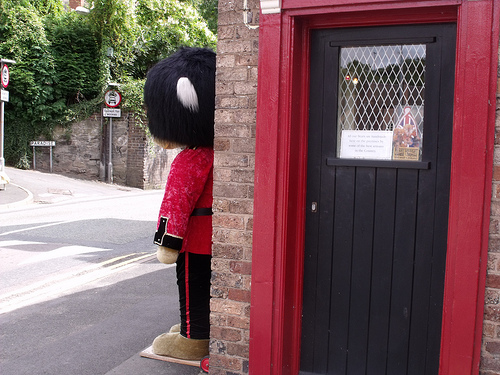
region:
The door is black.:
[307, 179, 387, 343]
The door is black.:
[336, 227, 399, 362]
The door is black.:
[322, 58, 437, 370]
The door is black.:
[303, 48, 398, 320]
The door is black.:
[360, 130, 400, 330]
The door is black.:
[365, 80, 432, 341]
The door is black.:
[365, 171, 413, 369]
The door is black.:
[357, 214, 394, 342]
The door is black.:
[330, 192, 347, 313]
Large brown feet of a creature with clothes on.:
[147, 320, 209, 359]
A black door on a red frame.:
[293, 17, 459, 374]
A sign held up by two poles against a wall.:
[27, 139, 57, 173]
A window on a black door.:
[332, 39, 428, 169]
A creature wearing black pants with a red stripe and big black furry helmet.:
[143, 43, 215, 359]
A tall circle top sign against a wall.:
[99, 86, 120, 183]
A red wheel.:
[198, 352, 211, 374]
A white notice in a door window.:
[336, 129, 394, 161]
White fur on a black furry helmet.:
[175, 78, 201, 115]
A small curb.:
[0, 179, 38, 206]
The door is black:
[328, 205, 409, 349]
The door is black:
[368, 183, 421, 278]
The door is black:
[286, 213, 379, 373]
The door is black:
[356, 153, 396, 315]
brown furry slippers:
[149, 317, 199, 373]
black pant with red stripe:
[156, 249, 208, 349]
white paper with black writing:
[336, 131, 403, 178]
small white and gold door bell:
[296, 195, 323, 237]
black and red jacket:
[126, 145, 214, 278]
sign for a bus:
[91, 84, 134, 110]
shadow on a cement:
[1, 182, 163, 326]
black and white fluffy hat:
[123, 82, 210, 157]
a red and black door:
[238, 118, 498, 373]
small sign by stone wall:
[13, 123, 65, 188]